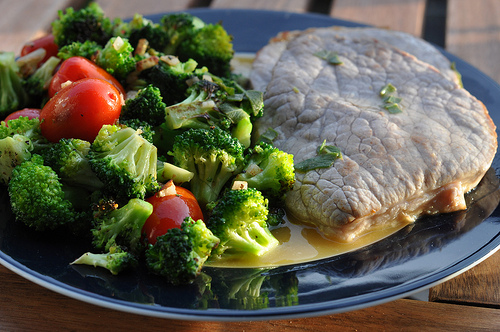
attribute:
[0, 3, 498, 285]
meal — cooked, outdoors, tossed, coursed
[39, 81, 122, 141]
tomato — grape, cooked, red, cherry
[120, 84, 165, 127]
broccoli — cooked, green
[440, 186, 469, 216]
meat — cooked, halfcooked, pieced, well cooked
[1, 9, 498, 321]
plate — blue, yellow, round, white, black, ceramic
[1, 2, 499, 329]
table — wooden, brown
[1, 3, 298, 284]
vegetables — green, piled